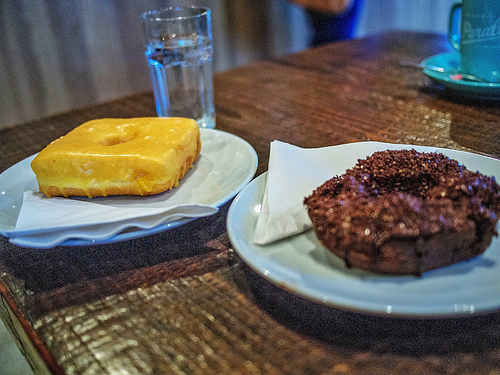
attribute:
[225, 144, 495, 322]
plate — white, round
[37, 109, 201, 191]
doughnut — square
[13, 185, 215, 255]
napkin — white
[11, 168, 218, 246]
napkin — white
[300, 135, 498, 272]
donut — yellow, square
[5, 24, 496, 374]
table — white, wooden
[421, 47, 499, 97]
plate — round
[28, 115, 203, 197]
donut — yellow, square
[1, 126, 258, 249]
plate — round, white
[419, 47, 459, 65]
plate — white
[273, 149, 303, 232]
napkin — white